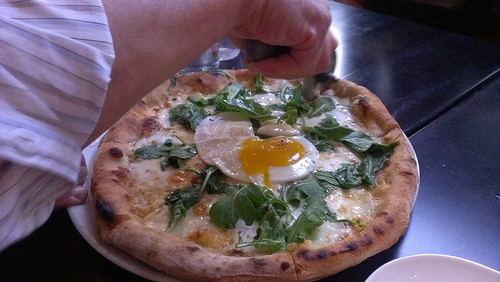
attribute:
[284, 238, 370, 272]
crust — browned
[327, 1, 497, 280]
table — whiny, wood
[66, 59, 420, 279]
plate — white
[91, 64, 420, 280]
pizza — personal sized, gourmet, scrumptious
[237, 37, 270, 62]
handle — bottom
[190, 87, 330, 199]
yolk — broken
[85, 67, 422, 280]
pizza crust — golden, brown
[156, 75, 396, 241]
leaves — green, arugula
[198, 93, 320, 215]
egg — fried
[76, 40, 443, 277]
pizza — brown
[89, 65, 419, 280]
crust — burnt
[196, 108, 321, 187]
egg — cooked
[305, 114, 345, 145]
leaf — spinach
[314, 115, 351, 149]
leaf — spinach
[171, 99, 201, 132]
leaf — spinach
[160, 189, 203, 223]
leaf — spinach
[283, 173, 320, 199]
leaf — spinach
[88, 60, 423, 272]
pie — pizza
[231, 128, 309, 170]
yolk — broken